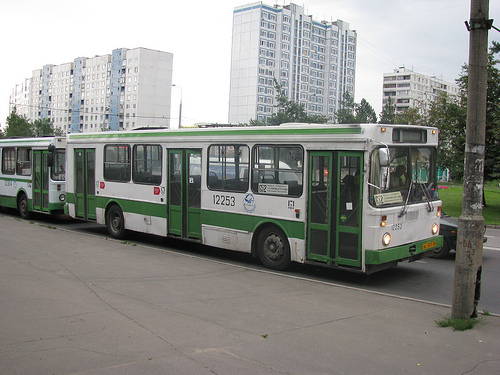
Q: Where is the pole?
A: To the right of the bus.